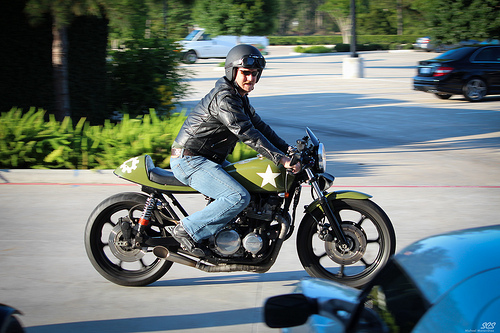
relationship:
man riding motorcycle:
[168, 41, 304, 261] [83, 123, 397, 288]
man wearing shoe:
[168, 41, 304, 261] [166, 222, 208, 259]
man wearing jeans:
[168, 41, 304, 261] [171, 149, 252, 247]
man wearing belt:
[168, 41, 304, 261] [169, 147, 202, 158]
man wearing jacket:
[168, 41, 304, 261] [170, 74, 291, 167]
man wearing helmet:
[168, 41, 304, 261] [222, 42, 269, 84]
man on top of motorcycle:
[168, 41, 304, 261] [83, 123, 397, 288]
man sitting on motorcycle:
[168, 41, 304, 261] [83, 123, 397, 288]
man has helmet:
[168, 41, 304, 261] [222, 42, 269, 84]